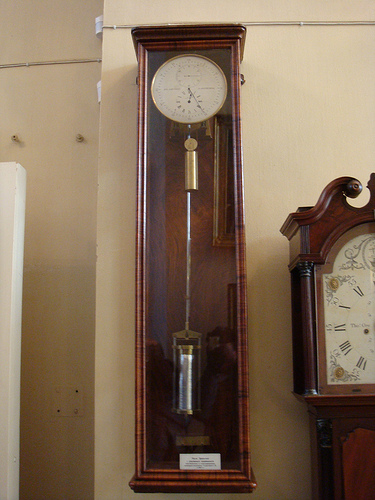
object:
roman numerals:
[351, 284, 365, 298]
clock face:
[149, 48, 229, 126]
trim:
[128, 23, 246, 47]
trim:
[278, 174, 361, 243]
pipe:
[0, 56, 102, 72]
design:
[337, 232, 375, 272]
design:
[326, 350, 362, 385]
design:
[324, 271, 356, 306]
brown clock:
[127, 21, 257, 497]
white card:
[179, 452, 221, 470]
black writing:
[183, 454, 219, 471]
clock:
[279, 169, 375, 409]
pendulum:
[171, 319, 203, 417]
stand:
[304, 405, 375, 500]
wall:
[92, 0, 374, 500]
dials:
[150, 52, 228, 124]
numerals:
[337, 305, 352, 311]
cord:
[0, 56, 102, 72]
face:
[321, 232, 375, 387]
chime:
[168, 125, 204, 418]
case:
[307, 405, 375, 500]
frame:
[127, 22, 258, 495]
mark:
[332, 366, 345, 381]